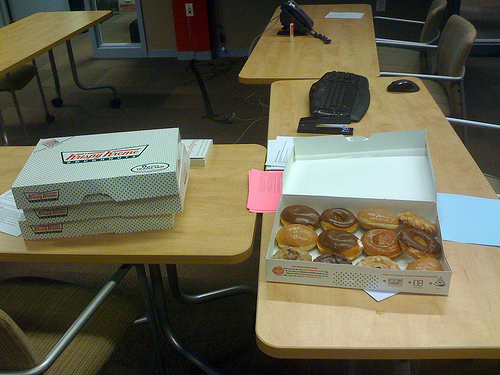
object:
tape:
[188, 59, 232, 125]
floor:
[0, 0, 498, 374]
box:
[260, 131, 450, 296]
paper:
[247, 168, 285, 214]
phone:
[279, 1, 333, 45]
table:
[239, 4, 380, 79]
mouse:
[386, 79, 419, 93]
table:
[268, 77, 496, 359]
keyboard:
[309, 71, 370, 121]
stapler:
[296, 115, 353, 136]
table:
[0, 142, 267, 259]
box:
[10, 155, 191, 240]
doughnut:
[280, 205, 422, 259]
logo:
[59, 144, 148, 164]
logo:
[24, 188, 59, 202]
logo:
[30, 223, 64, 234]